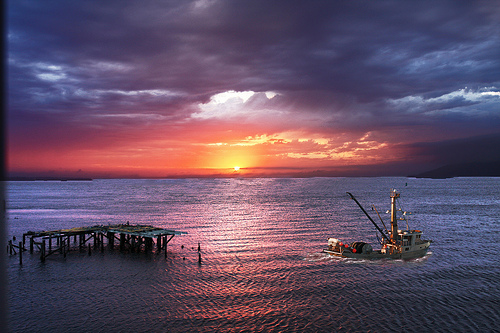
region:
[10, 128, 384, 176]
Orange sunset on the horizon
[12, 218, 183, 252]
Pier standing in water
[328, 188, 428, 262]
Boat moving through water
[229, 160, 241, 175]
Orange sun on the horizon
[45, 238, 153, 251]
Wooden supports under a pier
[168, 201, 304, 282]
Sun reflection on the water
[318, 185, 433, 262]
Fishing boat on water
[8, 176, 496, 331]
Calm ocean bay at sunset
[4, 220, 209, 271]
Delapitated wooden pier in water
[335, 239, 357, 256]
Orange buoys on boat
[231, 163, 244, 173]
Sun setting on horizon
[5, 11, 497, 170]
Cloudy sky at sunset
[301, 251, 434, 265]
Wake in water caused by boat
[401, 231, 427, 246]
Pilot house on fishing boat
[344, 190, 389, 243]
Metal crane on fishing boat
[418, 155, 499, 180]
land outcropping in background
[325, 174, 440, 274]
fishing boat in ocean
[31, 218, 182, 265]
black structure in ocean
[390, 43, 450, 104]
white clouds in gray sky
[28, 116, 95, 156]
white clouds in gray sky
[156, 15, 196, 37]
white clouds in gray sky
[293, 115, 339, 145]
white clouds in gray sky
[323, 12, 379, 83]
white clouds in gray sky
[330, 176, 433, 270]
boat in ocean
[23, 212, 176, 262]
structure in ocean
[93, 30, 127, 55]
white clouds in blue sky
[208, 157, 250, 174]
yellow sunset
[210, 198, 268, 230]
ripples in blue ocean water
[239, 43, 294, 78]
white clouds in blue sky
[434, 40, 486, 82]
white clouds in blue sky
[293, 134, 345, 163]
white clouds in yellow sky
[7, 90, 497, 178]
sun setting on the horizon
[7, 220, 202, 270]
pier in the water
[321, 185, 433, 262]
boat in the water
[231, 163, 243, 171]
sun in the sky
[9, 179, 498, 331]
water with ripples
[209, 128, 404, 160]
yellow and orange clouds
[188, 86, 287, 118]
white cloud in the sky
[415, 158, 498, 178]
land mass near water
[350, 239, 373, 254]
spool of cable on boat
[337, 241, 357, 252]
red objects on the boat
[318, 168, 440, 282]
fishing boat in ocean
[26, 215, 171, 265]
black structure in ocean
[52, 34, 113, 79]
white clouds in gray sky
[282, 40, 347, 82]
white clouds in gray sky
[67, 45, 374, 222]
this is a sunset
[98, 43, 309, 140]
the sky is very cloudy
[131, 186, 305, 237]
the water is orange and blue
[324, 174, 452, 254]
this is a large boat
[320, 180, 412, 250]
the mast is tall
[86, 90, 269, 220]
the sky is purple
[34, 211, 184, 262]
the platform metal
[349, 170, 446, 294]
a boat in the water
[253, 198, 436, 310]
a body of water that is calm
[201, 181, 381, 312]
a body of water with a boat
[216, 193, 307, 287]
a body of water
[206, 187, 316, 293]
an area of water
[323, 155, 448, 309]
a boat for shrimping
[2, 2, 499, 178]
cloudy sky at sunset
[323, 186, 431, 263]
sailing fishing boat